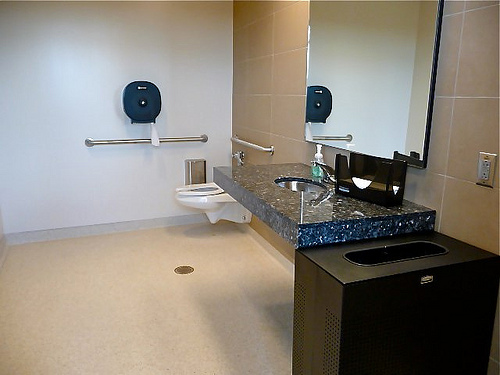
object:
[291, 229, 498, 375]
cabinet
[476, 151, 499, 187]
electrical outlet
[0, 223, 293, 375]
floor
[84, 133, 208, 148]
bar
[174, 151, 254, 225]
commode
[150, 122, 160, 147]
paper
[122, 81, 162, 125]
holder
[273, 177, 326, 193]
silver sink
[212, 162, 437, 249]
granite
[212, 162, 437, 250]
counter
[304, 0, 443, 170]
mirror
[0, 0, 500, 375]
restroom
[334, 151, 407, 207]
holder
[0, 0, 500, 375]
bathroom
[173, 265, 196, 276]
drain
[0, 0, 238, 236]
wall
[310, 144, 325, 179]
bottle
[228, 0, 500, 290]
wall